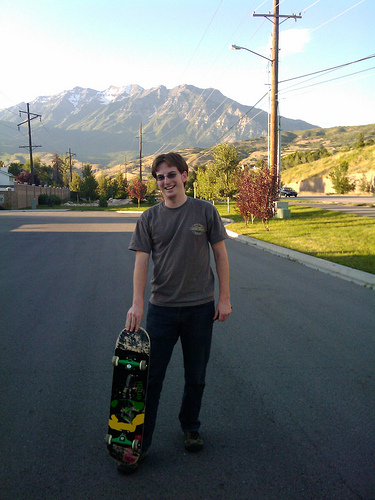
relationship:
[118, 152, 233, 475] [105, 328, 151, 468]
man holding skateboard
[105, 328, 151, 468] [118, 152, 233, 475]
skateboard held by man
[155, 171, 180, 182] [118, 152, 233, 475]
glasses are on man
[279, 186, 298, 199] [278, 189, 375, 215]
car on road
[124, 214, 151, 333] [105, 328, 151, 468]
arm holding skateboard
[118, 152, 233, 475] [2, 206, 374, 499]
man standing on street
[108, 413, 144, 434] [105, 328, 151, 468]
paint on skateboard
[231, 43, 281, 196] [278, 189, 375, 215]
light post on road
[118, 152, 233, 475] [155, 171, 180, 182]
man wearing glasses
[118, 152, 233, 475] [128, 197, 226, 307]
man wearing shirt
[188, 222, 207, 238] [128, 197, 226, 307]
logo on shirt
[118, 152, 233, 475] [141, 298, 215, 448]
man wearing jeans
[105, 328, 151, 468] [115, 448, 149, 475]
skateboard on foot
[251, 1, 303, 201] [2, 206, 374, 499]
power pole on side of street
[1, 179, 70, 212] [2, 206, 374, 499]
fence along street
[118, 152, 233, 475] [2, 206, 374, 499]
man in middle of street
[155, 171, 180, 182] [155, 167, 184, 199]
glasses are on face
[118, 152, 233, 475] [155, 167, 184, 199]
man has face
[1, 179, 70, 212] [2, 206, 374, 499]
fence close to street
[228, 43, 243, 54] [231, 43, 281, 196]
streetlight on light post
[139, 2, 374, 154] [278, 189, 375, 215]
power lines are along road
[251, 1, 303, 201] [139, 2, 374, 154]
power pole has power lines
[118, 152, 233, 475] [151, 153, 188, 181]
man has hair